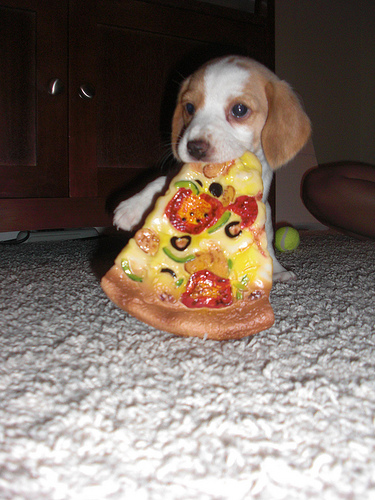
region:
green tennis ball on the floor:
[275, 226, 299, 251]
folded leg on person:
[297, 159, 374, 231]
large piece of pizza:
[104, 152, 275, 335]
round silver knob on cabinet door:
[46, 77, 63, 97]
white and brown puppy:
[111, 54, 309, 285]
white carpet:
[4, 231, 373, 496]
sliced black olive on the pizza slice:
[170, 234, 189, 250]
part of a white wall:
[274, 2, 370, 225]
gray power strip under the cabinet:
[17, 227, 97, 240]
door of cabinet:
[1, 3, 66, 198]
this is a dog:
[101, 47, 312, 342]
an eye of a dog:
[228, 96, 254, 123]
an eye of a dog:
[178, 95, 205, 125]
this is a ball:
[260, 214, 305, 265]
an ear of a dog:
[260, 74, 314, 184]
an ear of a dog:
[170, 81, 201, 156]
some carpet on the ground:
[35, 323, 116, 409]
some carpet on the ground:
[197, 386, 252, 472]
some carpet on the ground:
[66, 359, 139, 451]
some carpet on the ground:
[286, 361, 320, 449]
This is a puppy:
[136, 30, 320, 356]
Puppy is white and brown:
[89, 30, 326, 308]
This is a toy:
[95, 146, 290, 350]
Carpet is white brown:
[37, 323, 363, 495]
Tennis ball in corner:
[275, 220, 313, 260]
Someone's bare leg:
[304, 138, 374, 240]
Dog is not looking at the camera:
[171, 78, 274, 133]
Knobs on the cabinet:
[27, 52, 104, 118]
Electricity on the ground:
[15, 227, 113, 247]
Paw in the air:
[104, 184, 181, 238]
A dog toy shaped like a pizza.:
[98, 147, 273, 339]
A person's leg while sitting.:
[292, 153, 369, 236]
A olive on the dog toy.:
[167, 230, 189, 249]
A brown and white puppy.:
[105, 50, 312, 283]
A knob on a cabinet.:
[75, 70, 95, 101]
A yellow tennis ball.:
[271, 220, 301, 253]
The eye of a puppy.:
[225, 97, 251, 122]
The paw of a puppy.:
[105, 169, 167, 233]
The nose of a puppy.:
[182, 135, 215, 162]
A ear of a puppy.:
[258, 78, 315, 170]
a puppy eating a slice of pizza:
[102, 55, 312, 340]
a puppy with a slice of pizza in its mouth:
[102, 53, 312, 339]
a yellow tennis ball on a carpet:
[272, 224, 299, 255]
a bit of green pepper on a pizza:
[172, 179, 199, 195]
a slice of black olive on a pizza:
[223, 219, 241, 237]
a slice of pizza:
[100, 152, 275, 339]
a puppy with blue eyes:
[185, 99, 248, 118]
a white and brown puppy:
[113, 55, 312, 282]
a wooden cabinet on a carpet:
[0, 7, 274, 229]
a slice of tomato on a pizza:
[166, 188, 222, 231]